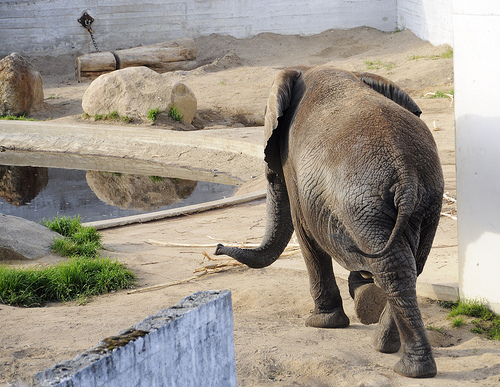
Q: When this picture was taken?
A: During the day.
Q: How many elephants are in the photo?
A: One.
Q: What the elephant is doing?
A: Walking.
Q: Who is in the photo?
A: A elephant.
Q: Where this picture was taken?
A: In a zoo.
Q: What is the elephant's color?
A: Gray.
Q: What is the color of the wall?
A: White.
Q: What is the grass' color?
A: Green.